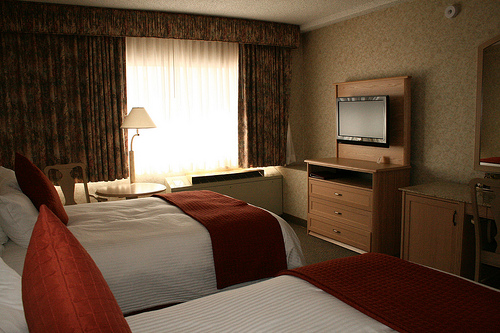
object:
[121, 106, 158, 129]
lamp shade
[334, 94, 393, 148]
black tv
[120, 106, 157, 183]
lamp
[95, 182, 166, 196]
table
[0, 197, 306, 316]
comforter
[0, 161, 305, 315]
bed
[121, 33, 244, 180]
window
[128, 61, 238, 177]
sunlight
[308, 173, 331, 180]
notebook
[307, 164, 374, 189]
shelf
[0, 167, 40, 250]
pillow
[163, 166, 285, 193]
large unit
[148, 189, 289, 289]
blanket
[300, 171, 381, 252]
drawers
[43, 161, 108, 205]
wooden chair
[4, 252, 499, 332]
bed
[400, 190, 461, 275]
door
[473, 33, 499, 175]
mirror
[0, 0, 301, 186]
curtain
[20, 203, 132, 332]
pillow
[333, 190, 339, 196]
knob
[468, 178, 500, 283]
chair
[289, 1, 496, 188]
wall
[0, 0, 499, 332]
photo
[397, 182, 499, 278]
desk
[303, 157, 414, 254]
cabinet